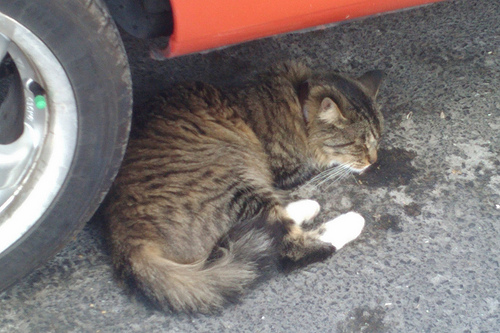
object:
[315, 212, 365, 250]
feet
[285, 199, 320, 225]
feet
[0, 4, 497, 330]
road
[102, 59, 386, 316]
cat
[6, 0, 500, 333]
ground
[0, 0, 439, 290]
car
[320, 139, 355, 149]
eyes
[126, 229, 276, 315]
tail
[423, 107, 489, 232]
cement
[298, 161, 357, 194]
white whiskers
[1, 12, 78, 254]
rim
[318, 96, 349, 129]
ear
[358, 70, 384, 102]
ear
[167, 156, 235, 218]
black stripes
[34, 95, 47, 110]
air cap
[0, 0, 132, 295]
tire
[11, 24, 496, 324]
concrete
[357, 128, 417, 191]
spot